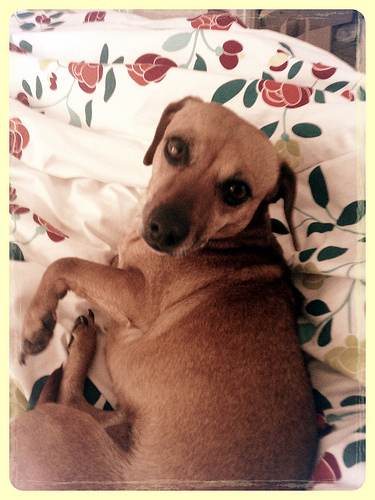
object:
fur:
[168, 340, 223, 425]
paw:
[19, 302, 62, 359]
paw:
[60, 303, 101, 364]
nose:
[144, 205, 189, 250]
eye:
[162, 132, 196, 170]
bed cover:
[9, 11, 363, 488]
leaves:
[306, 165, 329, 217]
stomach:
[102, 329, 187, 454]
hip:
[9, 398, 125, 490]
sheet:
[5, 9, 371, 492]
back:
[274, 281, 332, 493]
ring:
[218, 168, 252, 213]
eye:
[217, 169, 253, 205]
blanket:
[8, 11, 374, 494]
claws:
[65, 310, 103, 356]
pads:
[20, 313, 57, 360]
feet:
[16, 294, 56, 358]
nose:
[139, 207, 188, 254]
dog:
[8, 93, 317, 496]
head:
[140, 93, 303, 261]